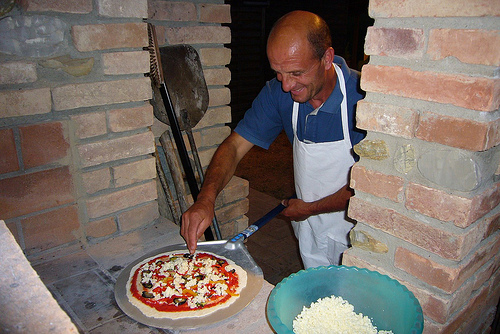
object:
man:
[178, 8, 360, 266]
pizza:
[125, 247, 250, 319]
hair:
[306, 19, 334, 62]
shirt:
[233, 56, 366, 150]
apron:
[288, 62, 355, 266]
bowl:
[264, 263, 425, 334]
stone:
[33, 218, 265, 333]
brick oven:
[0, 219, 81, 333]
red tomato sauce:
[147, 304, 191, 311]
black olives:
[140, 278, 155, 301]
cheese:
[293, 295, 396, 334]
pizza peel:
[113, 235, 262, 333]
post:
[340, 0, 497, 331]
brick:
[360, 66, 500, 113]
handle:
[229, 202, 281, 245]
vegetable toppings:
[139, 264, 160, 300]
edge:
[268, 263, 407, 293]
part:
[2, 0, 102, 130]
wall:
[1, 0, 151, 236]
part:
[159, 130, 176, 160]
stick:
[158, 128, 188, 209]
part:
[255, 203, 278, 229]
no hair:
[266, 8, 310, 55]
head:
[262, 10, 329, 105]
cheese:
[167, 257, 191, 278]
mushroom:
[173, 294, 188, 306]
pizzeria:
[2, 1, 499, 330]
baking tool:
[147, 22, 224, 239]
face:
[267, 42, 317, 102]